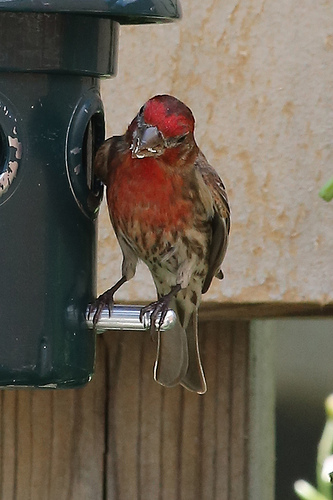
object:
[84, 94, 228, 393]
bird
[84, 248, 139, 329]
leg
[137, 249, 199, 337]
leg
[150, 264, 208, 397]
tail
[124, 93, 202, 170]
head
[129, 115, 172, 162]
peak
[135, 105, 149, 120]
eye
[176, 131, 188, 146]
eye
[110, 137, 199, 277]
chest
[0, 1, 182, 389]
feeder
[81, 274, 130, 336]
foot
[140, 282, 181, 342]
foot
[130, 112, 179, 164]
beak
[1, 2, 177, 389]
birdhouse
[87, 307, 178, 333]
handle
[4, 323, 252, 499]
slats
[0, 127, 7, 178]
hole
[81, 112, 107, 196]
hole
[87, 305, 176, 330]
pole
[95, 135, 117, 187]
wing